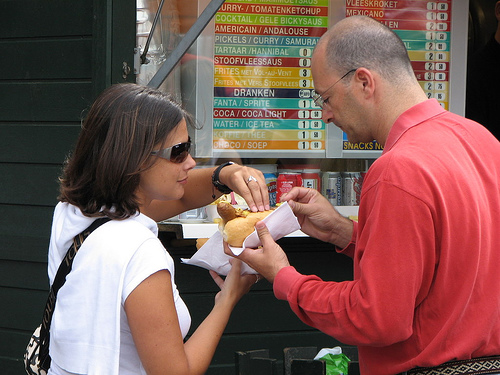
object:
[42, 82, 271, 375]
woman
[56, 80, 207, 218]
dark hair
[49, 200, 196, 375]
white shirt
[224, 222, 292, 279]
hand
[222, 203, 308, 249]
hot dog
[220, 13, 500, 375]
man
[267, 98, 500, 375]
red shirt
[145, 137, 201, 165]
sunglasses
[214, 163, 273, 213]
hand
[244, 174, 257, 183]
ring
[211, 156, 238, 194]
watch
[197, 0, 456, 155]
sign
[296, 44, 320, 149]
price(s)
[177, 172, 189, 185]
mouth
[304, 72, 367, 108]
glasses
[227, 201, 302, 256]
napkin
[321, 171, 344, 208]
can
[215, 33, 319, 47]
text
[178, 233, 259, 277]
white napkin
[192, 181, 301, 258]
eaten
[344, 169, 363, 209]
soda can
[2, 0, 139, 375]
wall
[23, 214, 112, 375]
purse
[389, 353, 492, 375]
diamond style belt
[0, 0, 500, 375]
stand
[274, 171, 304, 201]
beer